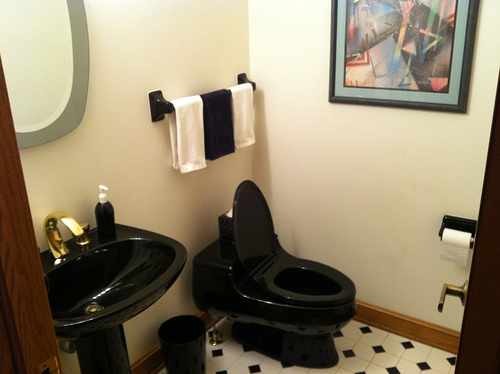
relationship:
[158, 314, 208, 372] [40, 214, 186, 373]
trash can next to sink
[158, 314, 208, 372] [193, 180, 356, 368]
trash can next to toilet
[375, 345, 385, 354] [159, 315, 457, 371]
diamond on floor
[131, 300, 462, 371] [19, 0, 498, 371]
base next to wall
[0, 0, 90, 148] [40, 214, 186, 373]
mirror above sink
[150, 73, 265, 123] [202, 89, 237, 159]
towel rack has towel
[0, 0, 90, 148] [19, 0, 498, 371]
mirror on wall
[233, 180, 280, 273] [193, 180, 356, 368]
lid up on toilet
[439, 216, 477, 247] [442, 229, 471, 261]
toilet paper rack with toilet paper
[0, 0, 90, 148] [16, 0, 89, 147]
mirror has silver frame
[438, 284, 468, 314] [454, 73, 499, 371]
handle on door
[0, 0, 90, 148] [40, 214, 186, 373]
mirror over sink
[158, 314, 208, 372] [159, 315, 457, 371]
trash can on floor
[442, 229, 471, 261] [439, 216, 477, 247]
toilet paper and toilet paper rack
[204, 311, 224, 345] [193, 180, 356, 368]
water pipe to toilet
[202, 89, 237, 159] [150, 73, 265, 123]
towel on towel rack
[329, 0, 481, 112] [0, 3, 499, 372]
picture in bathroom